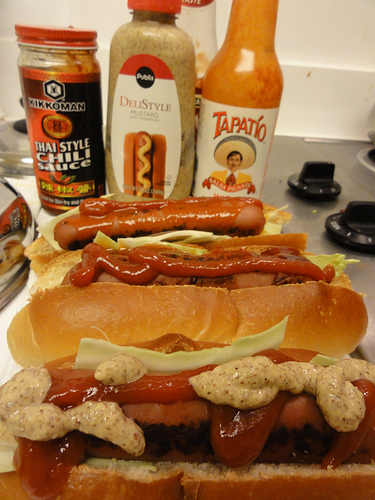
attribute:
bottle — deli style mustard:
[102, 0, 211, 210]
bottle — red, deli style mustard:
[106, 15, 193, 196]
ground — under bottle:
[297, 131, 317, 159]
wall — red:
[195, 60, 240, 104]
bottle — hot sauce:
[197, 0, 284, 210]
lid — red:
[10, 17, 97, 52]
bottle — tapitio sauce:
[189, 1, 291, 215]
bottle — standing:
[177, 1, 215, 129]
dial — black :
[288, 158, 345, 201]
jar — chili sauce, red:
[13, 21, 108, 214]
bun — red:
[67, 172, 353, 370]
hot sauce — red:
[186, 0, 285, 199]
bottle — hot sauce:
[207, 0, 285, 209]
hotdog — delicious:
[69, 195, 313, 228]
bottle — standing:
[114, 1, 195, 207]